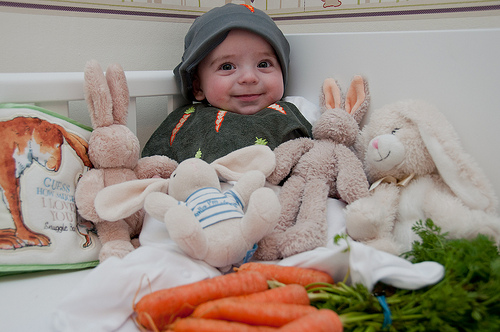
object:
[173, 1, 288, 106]
grey hat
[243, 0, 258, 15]
orange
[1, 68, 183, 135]
headboard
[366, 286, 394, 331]
tie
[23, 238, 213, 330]
blankets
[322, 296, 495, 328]
leaves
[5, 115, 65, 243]
bunny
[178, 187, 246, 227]
white shirt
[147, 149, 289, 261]
stuffed animal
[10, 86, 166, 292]
blanke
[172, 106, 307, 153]
costume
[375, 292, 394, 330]
rubber bands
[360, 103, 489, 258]
rabbit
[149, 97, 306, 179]
white bib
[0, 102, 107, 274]
bib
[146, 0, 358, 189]
baby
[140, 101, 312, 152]
clothing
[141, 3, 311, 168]
kid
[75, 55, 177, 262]
stuffed animal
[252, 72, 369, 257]
stuffed animal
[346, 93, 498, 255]
stuffed bunny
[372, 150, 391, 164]
smile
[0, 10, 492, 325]
bed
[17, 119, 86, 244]
orange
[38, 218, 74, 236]
letters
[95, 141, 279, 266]
bunny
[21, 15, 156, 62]
wall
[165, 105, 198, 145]
carrots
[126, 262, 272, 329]
carrot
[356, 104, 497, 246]
bunny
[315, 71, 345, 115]
ears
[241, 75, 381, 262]
stuffed rabbit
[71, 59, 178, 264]
bunny rabbit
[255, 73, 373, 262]
bunny rabbit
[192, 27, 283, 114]
head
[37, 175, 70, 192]
letters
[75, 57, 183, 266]
animal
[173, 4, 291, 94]
cap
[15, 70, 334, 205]
crib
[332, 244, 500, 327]
tops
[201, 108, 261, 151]
bib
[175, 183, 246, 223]
shirt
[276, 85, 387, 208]
rabbit